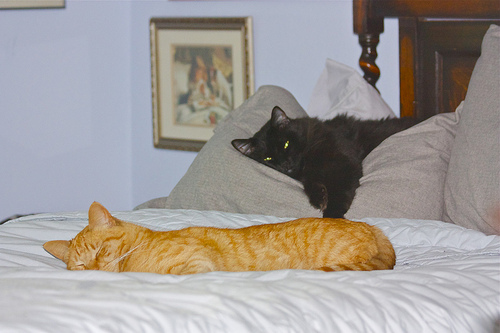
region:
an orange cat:
[42, 202, 402, 271]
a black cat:
[230, 123, 370, 218]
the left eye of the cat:
[283, 134, 293, 149]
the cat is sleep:
[45, 198, 410, 273]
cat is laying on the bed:
[55, 208, 394, 275]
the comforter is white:
[34, 284, 319, 319]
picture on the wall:
[148, 23, 248, 108]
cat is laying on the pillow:
[232, 120, 385, 209]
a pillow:
[444, 108, 499, 221]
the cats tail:
[319, 258, 378, 273]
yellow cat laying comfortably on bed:
[44, 201, 395, 269]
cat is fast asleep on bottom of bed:
[44, 200, 398, 273]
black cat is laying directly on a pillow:
[233, 104, 425, 216]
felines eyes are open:
[230, 104, 419, 218]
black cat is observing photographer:
[232, 101, 420, 216]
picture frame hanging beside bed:
[148, 15, 258, 150]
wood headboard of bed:
[351, 0, 498, 118]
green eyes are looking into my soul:
[261, 135, 295, 164]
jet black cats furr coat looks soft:
[233, 105, 413, 217]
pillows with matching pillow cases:
[166, 87, 448, 220]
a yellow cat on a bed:
[42, 211, 394, 283]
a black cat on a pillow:
[230, 89, 417, 229]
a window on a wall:
[147, 17, 250, 156]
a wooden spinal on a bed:
[352, 0, 387, 82]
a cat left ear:
[84, 198, 121, 231]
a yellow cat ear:
[39, 230, 73, 264]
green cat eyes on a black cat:
[262, 137, 299, 169]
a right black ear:
[222, 124, 254, 161]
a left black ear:
[264, 101, 293, 128]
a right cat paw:
[307, 183, 328, 215]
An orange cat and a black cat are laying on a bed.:
[42, 105, 448, 277]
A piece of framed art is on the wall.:
[147, 14, 262, 159]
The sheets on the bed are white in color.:
[1, 197, 494, 322]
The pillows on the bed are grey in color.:
[131, 19, 498, 238]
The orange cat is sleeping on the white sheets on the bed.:
[39, 199, 399, 278]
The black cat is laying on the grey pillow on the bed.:
[231, 102, 447, 223]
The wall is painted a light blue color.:
[1, 0, 398, 222]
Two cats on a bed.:
[37, 83, 442, 284]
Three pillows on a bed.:
[129, 15, 496, 238]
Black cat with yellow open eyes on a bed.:
[229, 98, 446, 220]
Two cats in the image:
[35, 82, 422, 281]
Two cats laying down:
[41, 103, 421, 277]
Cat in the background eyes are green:
[258, 131, 311, 176]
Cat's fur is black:
[227, 88, 423, 228]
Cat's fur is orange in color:
[40, 193, 401, 291]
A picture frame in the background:
[141, 8, 261, 167]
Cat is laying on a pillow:
[161, 77, 461, 227]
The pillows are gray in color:
[147, 30, 497, 225]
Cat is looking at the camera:
[228, 99, 308, 187]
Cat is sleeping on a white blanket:
[0, 195, 496, 331]